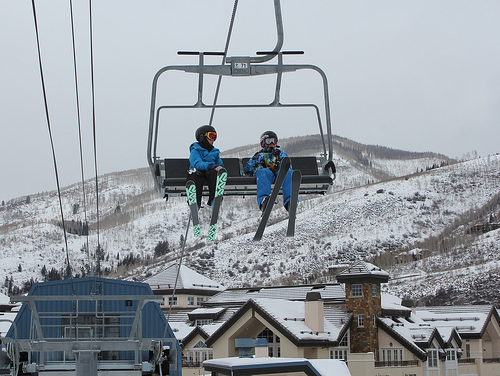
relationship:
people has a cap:
[186, 125, 227, 211] [195, 124, 217, 140]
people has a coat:
[186, 125, 227, 211] [191, 146, 225, 174]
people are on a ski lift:
[190, 127, 298, 208] [152, 67, 337, 198]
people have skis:
[190, 127, 298, 208] [185, 169, 225, 241]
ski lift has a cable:
[152, 67, 337, 198] [31, 3, 92, 297]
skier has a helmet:
[186, 125, 228, 242] [260, 130, 278, 148]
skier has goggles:
[186, 125, 228, 242] [206, 132, 219, 141]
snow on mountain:
[1, 135, 498, 307] [1, 132, 498, 305]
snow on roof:
[1, 135, 498, 307] [254, 298, 350, 341]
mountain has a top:
[1, 132, 498, 305] [221, 132, 454, 161]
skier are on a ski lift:
[185, 125, 229, 242] [152, 67, 337, 198]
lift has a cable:
[4, 296, 175, 373] [31, 3, 92, 297]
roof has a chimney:
[254, 298, 350, 341] [339, 260, 391, 350]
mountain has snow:
[1, 132, 498, 305] [1, 135, 498, 307]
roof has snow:
[254, 298, 350, 341] [1, 135, 498, 307]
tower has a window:
[346, 281, 381, 350] [358, 312, 365, 330]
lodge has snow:
[208, 258, 498, 375] [1, 135, 498, 307]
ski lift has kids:
[152, 67, 337, 198] [183, 124, 300, 240]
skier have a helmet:
[185, 125, 229, 242] [260, 130, 278, 148]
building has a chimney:
[5, 279, 181, 356] [339, 260, 391, 350]